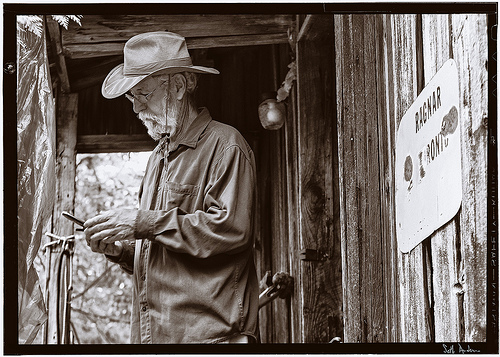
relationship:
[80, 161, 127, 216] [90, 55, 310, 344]
tree behind man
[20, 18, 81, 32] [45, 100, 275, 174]
leaves from rooftop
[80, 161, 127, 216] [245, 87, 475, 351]
tree behind cabin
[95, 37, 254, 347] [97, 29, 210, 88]
man wearing hat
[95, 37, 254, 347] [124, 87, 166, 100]
man wearing glasses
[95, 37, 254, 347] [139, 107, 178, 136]
man with beard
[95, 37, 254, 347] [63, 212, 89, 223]
man using cellphone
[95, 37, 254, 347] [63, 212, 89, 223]
man reading cellphone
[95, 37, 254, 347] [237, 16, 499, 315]
man in front of building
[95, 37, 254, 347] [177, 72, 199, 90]
man with hair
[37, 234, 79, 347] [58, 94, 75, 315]
rope on beam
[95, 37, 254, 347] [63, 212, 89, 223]
man holding cellphone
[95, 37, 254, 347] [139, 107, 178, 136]
man has beard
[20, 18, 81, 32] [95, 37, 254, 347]
leaves above man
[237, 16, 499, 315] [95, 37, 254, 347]
building behind man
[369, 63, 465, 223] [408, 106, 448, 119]
sign with writing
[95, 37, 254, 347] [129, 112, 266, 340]
man wearing shirt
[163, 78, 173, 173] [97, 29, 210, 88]
string on hat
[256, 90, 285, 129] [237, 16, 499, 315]
lamp on building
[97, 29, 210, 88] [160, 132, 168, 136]
hat has knob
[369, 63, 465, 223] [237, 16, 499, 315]
sign on building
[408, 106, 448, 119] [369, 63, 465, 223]
writing on sign